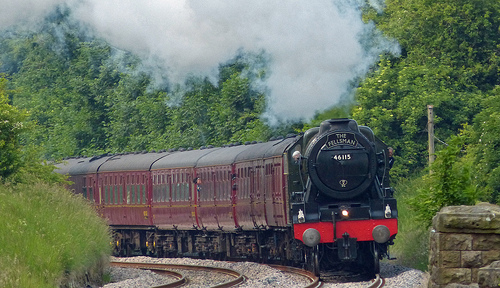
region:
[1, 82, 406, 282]
the train is in motion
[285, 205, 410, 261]
the front bottom of the train is red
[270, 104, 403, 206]
the front of the train is black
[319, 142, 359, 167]
numbers on the front of the train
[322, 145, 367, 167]
the numbers are white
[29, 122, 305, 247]
the train cars are burgundy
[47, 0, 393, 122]
smoke is coming from the train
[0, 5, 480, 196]
the trees are thick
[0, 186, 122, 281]
the grass is tall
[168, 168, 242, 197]
the conductors head is out the window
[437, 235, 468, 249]
brick of a stone wall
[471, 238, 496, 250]
brick of a stone wall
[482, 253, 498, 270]
brick of a stone wall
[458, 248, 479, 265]
brick of a stone wall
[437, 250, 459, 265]
brick of a stone wall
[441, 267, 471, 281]
brick of a stone wall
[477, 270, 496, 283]
brick of a stone wall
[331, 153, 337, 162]
white number on train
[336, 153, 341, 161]
white number on train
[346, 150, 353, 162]
white number on train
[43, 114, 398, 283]
a long passenger train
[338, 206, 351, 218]
a light on the front of a train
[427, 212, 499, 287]
a stone wall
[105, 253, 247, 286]
a curved train track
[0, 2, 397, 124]
smoke comes out of a train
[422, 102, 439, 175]
a wooden pole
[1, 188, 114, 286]
green grass on a hill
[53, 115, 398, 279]
a train travels around a curve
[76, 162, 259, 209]
windows to a passenger train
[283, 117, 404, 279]
the front of the train is black and red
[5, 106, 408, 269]
Train on tracks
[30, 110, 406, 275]
Train is on tracks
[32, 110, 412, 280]
Train on train tracks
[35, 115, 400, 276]
Train is on train tracks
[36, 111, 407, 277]
Train on railroad tracks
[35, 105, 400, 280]
Train is on railroad tracks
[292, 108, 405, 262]
Front of train is red and black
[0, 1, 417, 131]
Steam coming out of train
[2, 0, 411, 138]
Steam is coming out of train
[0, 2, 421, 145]
Steam is coming out of a train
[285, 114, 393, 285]
a red and black train engine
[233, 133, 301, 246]
a red and black train car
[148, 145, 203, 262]
a red and black train car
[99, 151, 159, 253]
a red and black train car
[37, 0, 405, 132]
smoke coming from a train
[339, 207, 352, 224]
the headlight of a train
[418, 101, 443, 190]
a wooden telephone pole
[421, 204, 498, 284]
a rock fence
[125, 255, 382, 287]
a group of railroad tracks